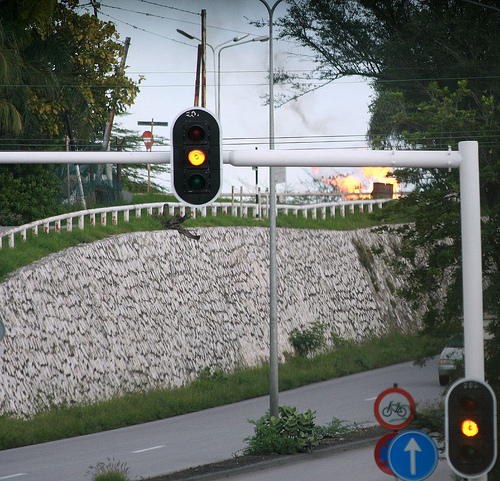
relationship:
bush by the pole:
[242, 405, 363, 455] [265, 167, 280, 418]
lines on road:
[129, 444, 166, 454] [0, 346, 485, 476]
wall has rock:
[5, 215, 498, 413] [109, 291, 299, 344]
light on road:
[169, 107, 222, 207] [2, 311, 499, 480]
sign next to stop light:
[385, 427, 440, 479] [443, 378, 497, 480]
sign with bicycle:
[365, 375, 423, 436] [371, 393, 419, 423]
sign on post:
[373, 432, 398, 477] [243, 139, 480, 377]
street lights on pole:
[180, 19, 284, 54] [206, 51, 226, 133]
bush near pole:
[242, 398, 323, 458] [268, 1, 280, 408]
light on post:
[169, 107, 222, 207] [226, 152, 485, 378]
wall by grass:
[5, 215, 498, 413] [123, 340, 388, 380]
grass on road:
[54, 405, 108, 432] [133, 407, 391, 474]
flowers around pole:
[40, 94, 62, 134] [269, 11, 291, 410]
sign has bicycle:
[374, 387, 416, 430] [382, 401, 407, 417]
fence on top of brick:
[5, 216, 83, 235] [44, 230, 375, 352]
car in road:
[438, 332, 493, 386] [346, 364, 433, 406]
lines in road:
[117, 440, 184, 458] [47, 225, 497, 459]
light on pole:
[163, 101, 259, 214] [460, 142, 485, 382]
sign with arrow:
[387, 429, 438, 481] [409, 441, 416, 479]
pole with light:
[53, 126, 484, 253] [169, 107, 222, 207]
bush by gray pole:
[242, 405, 363, 455] [261, 0, 281, 416]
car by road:
[437, 345, 488, 390] [5, 350, 459, 470]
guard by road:
[46, 177, 300, 285] [17, 132, 481, 457]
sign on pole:
[142, 131, 154, 147] [141, 148, 151, 195]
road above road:
[2, 351, 444, 478] [0, 221, 82, 232]